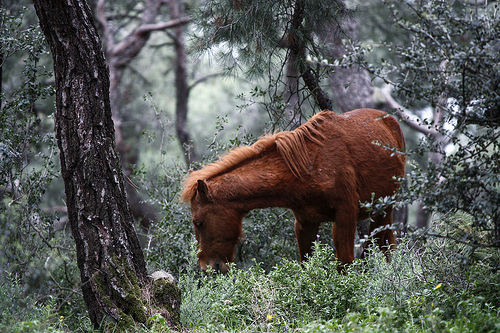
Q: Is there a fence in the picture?
A: No, there are no fences.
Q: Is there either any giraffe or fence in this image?
A: No, there are no fences or giraffes.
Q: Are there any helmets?
A: No, there are no helmets.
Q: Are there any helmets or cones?
A: No, there are no helmets or cones.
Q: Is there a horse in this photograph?
A: Yes, there is a horse.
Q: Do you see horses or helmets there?
A: Yes, there is a horse.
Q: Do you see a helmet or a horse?
A: Yes, there is a horse.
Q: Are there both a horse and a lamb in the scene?
A: No, there is a horse but no lambs.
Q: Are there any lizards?
A: No, there are no lizards.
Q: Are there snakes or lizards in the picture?
A: No, there are no lizards or snakes.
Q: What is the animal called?
A: The animal is a horse.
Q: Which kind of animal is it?
A: The animal is a horse.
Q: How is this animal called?
A: This is a horse.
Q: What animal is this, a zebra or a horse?
A: This is a horse.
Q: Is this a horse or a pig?
A: This is a horse.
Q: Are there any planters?
A: No, there are no planters.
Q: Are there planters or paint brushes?
A: No, there are no planters or paint brushes.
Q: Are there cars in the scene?
A: No, there are no cars.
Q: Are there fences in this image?
A: No, there are no fences.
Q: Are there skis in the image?
A: No, there are no skis.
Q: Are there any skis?
A: No, there are no skis.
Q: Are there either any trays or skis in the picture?
A: No, there are no skis or trays.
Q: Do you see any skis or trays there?
A: No, there are no skis or trays.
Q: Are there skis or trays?
A: No, there are no skis or trays.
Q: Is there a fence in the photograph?
A: No, there are no fences.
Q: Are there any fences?
A: No, there are no fences.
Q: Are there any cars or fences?
A: No, there are no fences or cars.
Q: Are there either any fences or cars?
A: No, there are no fences or cars.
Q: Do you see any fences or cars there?
A: No, there are no fences or cars.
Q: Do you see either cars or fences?
A: No, there are no fences or cars.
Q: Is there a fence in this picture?
A: No, there are no fences.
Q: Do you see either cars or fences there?
A: No, there are no fences or cars.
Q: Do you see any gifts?
A: No, there are no gifts.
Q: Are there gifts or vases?
A: No, there are no gifts or vases.